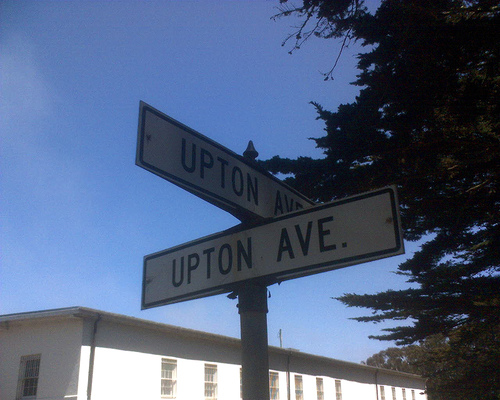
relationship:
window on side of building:
[16, 358, 41, 398] [6, 300, 437, 398]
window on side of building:
[335, 378, 343, 398] [6, 300, 437, 398]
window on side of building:
[401, 387, 406, 397] [6, 300, 437, 398]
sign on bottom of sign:
[140, 182, 409, 308] [133, 97, 319, 222]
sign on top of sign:
[94, 106, 354, 235] [98, 190, 429, 313]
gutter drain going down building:
[74, 308, 103, 398] [6, 300, 437, 398]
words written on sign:
[170, 215, 336, 285] [140, 182, 409, 308]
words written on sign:
[180, 137, 305, 215] [133, 97, 319, 222]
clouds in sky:
[1, 89, 82, 144] [5, 1, 397, 361]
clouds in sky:
[1, 21, 53, 126] [1, 2, 498, 364]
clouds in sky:
[5, 31, 148, 231] [71, 12, 264, 104]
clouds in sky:
[25, 163, 144, 279] [53, 69, 188, 94]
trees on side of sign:
[223, 3, 497, 399] [140, 183, 398, 308]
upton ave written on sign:
[159, 218, 345, 295] [140, 182, 409, 308]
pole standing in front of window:
[233, 139, 272, 399] [332, 380, 341, 397]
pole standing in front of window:
[233, 139, 272, 399] [202, 362, 216, 397]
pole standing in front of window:
[233, 139, 272, 399] [156, 354, 178, 396]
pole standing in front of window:
[233, 139, 272, 399] [292, 374, 305, 397]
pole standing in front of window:
[233, 139, 272, 399] [269, 372, 281, 397]